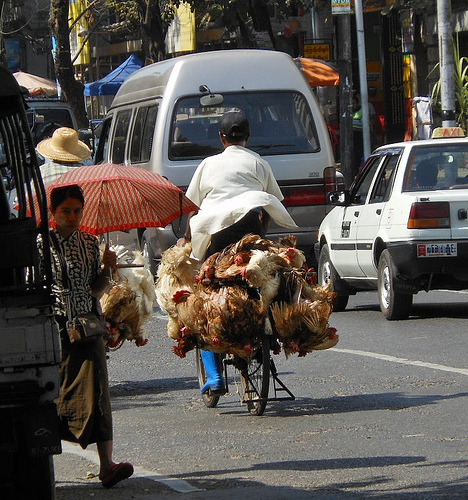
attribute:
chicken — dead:
[222, 293, 265, 362]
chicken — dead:
[279, 246, 306, 269]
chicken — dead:
[272, 272, 328, 350]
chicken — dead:
[171, 338, 195, 359]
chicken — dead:
[194, 252, 215, 286]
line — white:
[326, 345, 467, 379]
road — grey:
[55, 290, 467, 499]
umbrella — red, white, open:
[14, 162, 201, 281]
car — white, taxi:
[313, 137, 468, 320]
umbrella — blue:
[85, 53, 145, 94]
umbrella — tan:
[12, 70, 57, 95]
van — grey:
[94, 49, 337, 262]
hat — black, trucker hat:
[218, 112, 250, 139]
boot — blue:
[200, 350, 225, 392]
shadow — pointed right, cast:
[215, 391, 467, 416]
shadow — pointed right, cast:
[109, 368, 294, 411]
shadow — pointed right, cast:
[344, 302, 467, 320]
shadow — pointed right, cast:
[55, 455, 467, 499]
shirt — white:
[187, 145, 298, 259]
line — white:
[62, 440, 214, 495]